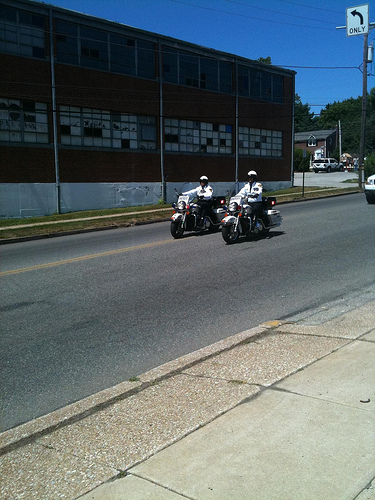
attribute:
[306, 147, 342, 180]
car — parked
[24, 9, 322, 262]
building — open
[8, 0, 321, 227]
building — large, abandoned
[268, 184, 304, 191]
grass — patch of grass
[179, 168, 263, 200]
policemen — riding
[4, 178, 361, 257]
curb — grassy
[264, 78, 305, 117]
ground — black 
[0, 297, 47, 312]
stain — dark 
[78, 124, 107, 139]
windows — broken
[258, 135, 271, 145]
windows — broken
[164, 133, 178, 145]
windows — broken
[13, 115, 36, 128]
windows — broken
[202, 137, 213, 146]
windows — broken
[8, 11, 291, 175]
building — brick building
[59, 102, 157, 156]
windows — broken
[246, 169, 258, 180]
helmet — white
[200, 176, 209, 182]
helmet — white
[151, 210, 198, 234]
wheel — front wheel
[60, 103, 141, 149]
window — broken